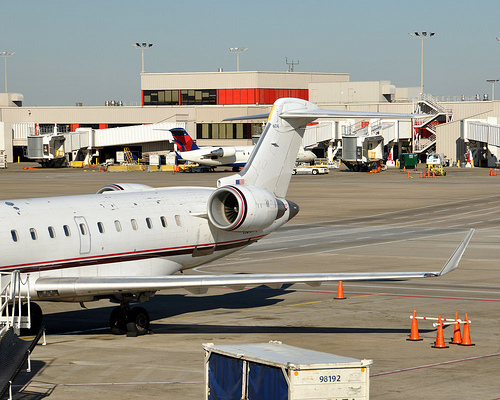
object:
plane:
[0, 97, 475, 336]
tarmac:
[0, 161, 499, 400]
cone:
[408, 308, 423, 342]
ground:
[0, 160, 499, 400]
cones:
[332, 279, 476, 347]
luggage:
[203, 332, 371, 400]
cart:
[204, 341, 374, 400]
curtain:
[207, 352, 290, 399]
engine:
[207, 185, 288, 232]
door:
[74, 216, 92, 254]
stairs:
[414, 95, 452, 158]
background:
[0, 0, 499, 400]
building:
[0, 72, 500, 166]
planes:
[151, 124, 317, 173]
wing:
[36, 228, 473, 298]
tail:
[168, 128, 199, 152]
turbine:
[222, 193, 239, 224]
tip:
[275, 199, 287, 221]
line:
[0, 236, 264, 278]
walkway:
[69, 118, 189, 150]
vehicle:
[292, 163, 330, 176]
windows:
[10, 229, 19, 242]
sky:
[1, 0, 500, 104]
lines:
[282, 290, 500, 303]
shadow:
[11, 284, 448, 337]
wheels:
[110, 306, 150, 338]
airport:
[0, 0, 500, 398]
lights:
[413, 31, 445, 38]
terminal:
[141, 73, 356, 107]